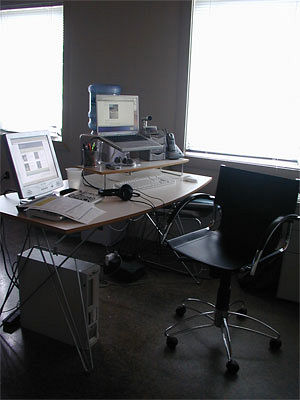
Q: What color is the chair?
A: Black.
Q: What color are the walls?
A: White.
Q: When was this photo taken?
A: Daytime.